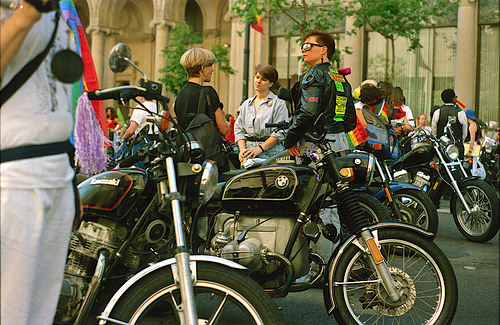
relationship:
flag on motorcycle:
[80, 57, 133, 176] [79, 132, 446, 313]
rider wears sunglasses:
[295, 35, 356, 285] [300, 36, 324, 51]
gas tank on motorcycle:
[202, 213, 305, 288] [79, 132, 446, 313]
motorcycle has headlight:
[79, 132, 446, 313] [336, 150, 385, 186]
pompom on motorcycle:
[74, 108, 112, 164] [79, 132, 446, 313]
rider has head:
[295, 35, 356, 285] [301, 27, 339, 63]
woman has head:
[172, 46, 225, 171] [182, 54, 213, 79]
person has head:
[232, 60, 289, 160] [250, 68, 278, 99]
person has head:
[293, 37, 347, 153] [301, 27, 339, 63]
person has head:
[432, 91, 462, 144] [441, 84, 459, 111]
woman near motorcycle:
[232, 60, 289, 160] [79, 132, 446, 313]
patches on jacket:
[333, 82, 346, 117] [282, 71, 357, 144]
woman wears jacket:
[293, 37, 347, 153] [282, 71, 357, 144]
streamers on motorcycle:
[74, 108, 112, 164] [79, 132, 446, 313]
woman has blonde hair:
[172, 56, 225, 134] [181, 50, 216, 68]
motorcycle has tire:
[79, 132, 446, 313] [100, 249, 274, 324]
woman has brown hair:
[232, 60, 289, 160] [249, 68, 278, 83]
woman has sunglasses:
[293, 37, 347, 153] [300, 36, 324, 51]